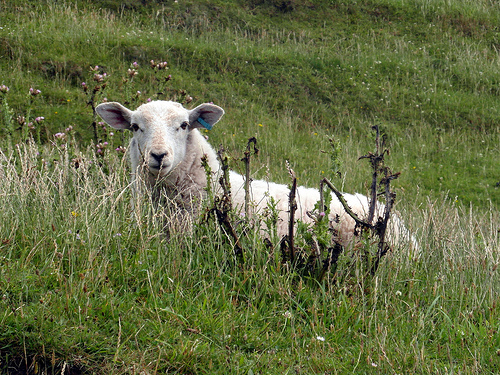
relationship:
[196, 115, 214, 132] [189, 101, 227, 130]
blue tag on ear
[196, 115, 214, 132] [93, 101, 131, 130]
blue tag on ear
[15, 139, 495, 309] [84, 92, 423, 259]
tall weeds in front of sheep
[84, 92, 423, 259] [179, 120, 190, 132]
sheep has eyes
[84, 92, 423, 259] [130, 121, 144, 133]
sheep has eyes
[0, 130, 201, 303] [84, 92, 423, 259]
grass in front of sheep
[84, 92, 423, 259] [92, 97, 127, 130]
sheep has ear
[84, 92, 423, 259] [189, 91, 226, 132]
sheep has ear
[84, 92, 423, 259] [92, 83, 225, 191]
sheep has head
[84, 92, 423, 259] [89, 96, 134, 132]
sheep has ear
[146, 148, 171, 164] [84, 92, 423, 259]
sheep nose on sheep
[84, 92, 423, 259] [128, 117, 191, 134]
sheep has eyes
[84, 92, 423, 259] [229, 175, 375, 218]
sheep has wool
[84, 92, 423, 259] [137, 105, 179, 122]
sheep has forehead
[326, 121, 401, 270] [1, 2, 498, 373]
twigs sprouted from ground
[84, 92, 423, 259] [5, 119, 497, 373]
sheep in grass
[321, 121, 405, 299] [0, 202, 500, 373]
plant grows in grass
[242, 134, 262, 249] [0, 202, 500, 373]
plant grows in grass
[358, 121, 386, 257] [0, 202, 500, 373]
plant grows in grass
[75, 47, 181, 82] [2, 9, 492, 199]
flowers in grass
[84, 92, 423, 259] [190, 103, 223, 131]
sheep has ear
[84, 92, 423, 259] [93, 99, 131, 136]
sheep has ear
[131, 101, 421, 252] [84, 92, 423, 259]
wool on sheep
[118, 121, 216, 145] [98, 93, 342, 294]
eyes on sheep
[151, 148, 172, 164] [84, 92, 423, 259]
sheep nose on sheep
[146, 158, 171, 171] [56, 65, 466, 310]
mouth of sheep